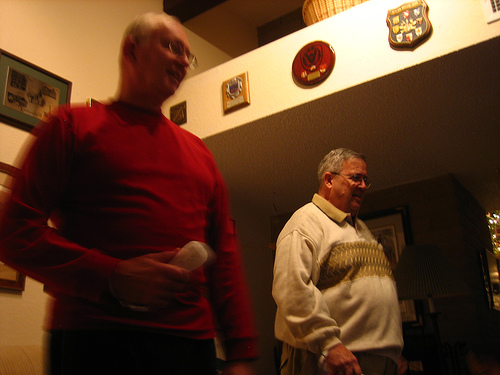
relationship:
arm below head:
[0, 103, 190, 301] [113, 12, 196, 104]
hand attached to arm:
[123, 252, 191, 307] [0, 103, 190, 301]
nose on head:
[180, 54, 190, 68] [113, 12, 196, 104]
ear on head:
[125, 35, 137, 63] [113, 12, 196, 104]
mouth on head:
[167, 68, 184, 84] [113, 12, 196, 104]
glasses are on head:
[168, 39, 198, 66] [113, 12, 196, 104]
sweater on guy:
[274, 204, 407, 349] [273, 149, 406, 373]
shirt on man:
[52, 109, 213, 332] [0, 14, 263, 371]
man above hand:
[0, 14, 263, 371] [123, 252, 191, 307]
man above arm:
[0, 14, 263, 371] [0, 103, 190, 301]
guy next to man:
[273, 149, 406, 373] [0, 14, 263, 371]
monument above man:
[292, 41, 335, 85] [0, 14, 263, 371]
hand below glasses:
[123, 252, 191, 307] [168, 39, 198, 66]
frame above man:
[0, 50, 72, 136] [0, 14, 263, 371]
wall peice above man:
[217, 72, 253, 112] [0, 14, 263, 371]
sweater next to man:
[274, 204, 407, 349] [0, 14, 263, 371]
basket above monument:
[300, 0, 361, 28] [292, 41, 335, 85]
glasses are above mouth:
[168, 39, 198, 66] [167, 68, 184, 84]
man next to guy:
[0, 14, 263, 371] [273, 149, 406, 373]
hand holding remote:
[123, 252, 191, 307] [175, 243, 207, 273]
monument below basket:
[292, 41, 335, 85] [300, 0, 361, 28]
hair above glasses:
[124, 9, 178, 38] [168, 39, 198, 66]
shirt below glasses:
[52, 109, 213, 332] [168, 39, 198, 66]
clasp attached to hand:
[106, 270, 129, 313] [123, 252, 191, 307]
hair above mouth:
[124, 9, 178, 38] [167, 68, 184, 84]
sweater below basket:
[274, 204, 407, 349] [300, 0, 361, 28]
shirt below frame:
[52, 109, 213, 332] [0, 50, 72, 136]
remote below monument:
[175, 243, 207, 273] [292, 41, 335, 85]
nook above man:
[180, 0, 298, 79] [0, 14, 263, 371]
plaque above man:
[386, 2, 432, 49] [0, 14, 263, 371]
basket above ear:
[300, 0, 361, 28] [125, 35, 137, 63]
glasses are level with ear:
[168, 39, 198, 66] [125, 35, 137, 63]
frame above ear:
[0, 50, 72, 136] [125, 35, 137, 63]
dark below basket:
[399, 175, 492, 373] [300, 0, 361, 28]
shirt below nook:
[52, 109, 213, 332] [180, 0, 298, 79]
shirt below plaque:
[52, 109, 213, 332] [386, 2, 432, 49]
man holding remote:
[0, 14, 263, 371] [175, 243, 207, 273]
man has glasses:
[0, 14, 263, 371] [168, 39, 198, 66]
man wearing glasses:
[0, 14, 263, 371] [168, 39, 198, 66]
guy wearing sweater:
[273, 149, 406, 373] [274, 204, 407, 349]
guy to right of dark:
[273, 149, 406, 373] [399, 175, 492, 373]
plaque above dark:
[386, 2, 432, 49] [399, 175, 492, 373]